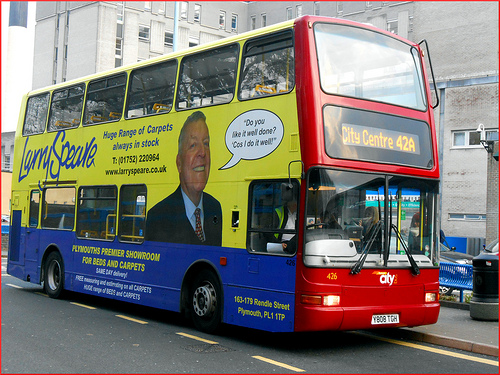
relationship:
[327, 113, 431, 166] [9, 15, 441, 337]
route on bus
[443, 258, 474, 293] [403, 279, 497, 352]
bench on sidewalk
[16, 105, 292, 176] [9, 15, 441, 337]
advertisements on bus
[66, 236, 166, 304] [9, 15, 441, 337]
advertisements on bus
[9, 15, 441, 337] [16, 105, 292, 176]
bus has advertisements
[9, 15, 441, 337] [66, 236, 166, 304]
bus has advertisements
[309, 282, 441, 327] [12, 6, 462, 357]
light on bus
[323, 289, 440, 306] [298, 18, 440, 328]
lights on front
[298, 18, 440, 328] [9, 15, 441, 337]
front of bus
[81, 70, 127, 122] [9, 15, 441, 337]
window of a bus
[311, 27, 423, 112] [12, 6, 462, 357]
window of a bus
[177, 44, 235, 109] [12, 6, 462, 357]
window of a bus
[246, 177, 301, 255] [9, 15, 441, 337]
window of a bus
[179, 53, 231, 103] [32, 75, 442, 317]
window of a bus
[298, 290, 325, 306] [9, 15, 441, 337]
lights on front of bus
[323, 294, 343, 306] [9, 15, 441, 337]
lights on front of bus